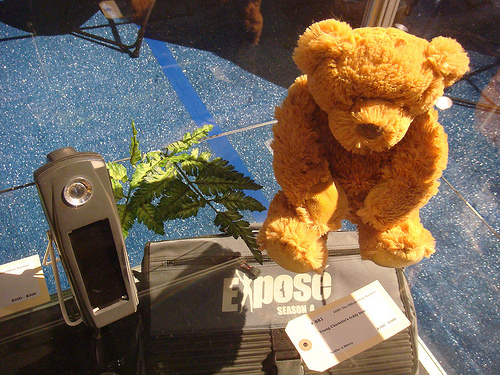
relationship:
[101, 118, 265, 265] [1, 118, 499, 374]
leaves on table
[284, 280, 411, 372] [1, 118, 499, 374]
tag on table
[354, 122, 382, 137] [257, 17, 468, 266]
nose on teddy bear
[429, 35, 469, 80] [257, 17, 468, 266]
ear on teddy bear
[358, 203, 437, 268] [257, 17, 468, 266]
leg on teddy bear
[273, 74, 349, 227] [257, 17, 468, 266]
arm on teddy bear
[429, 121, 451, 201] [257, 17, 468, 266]
light on teddy bear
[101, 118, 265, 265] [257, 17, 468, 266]
leaves beside teddy bear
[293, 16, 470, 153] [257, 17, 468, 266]
face on teddy bear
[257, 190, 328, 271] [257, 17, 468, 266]
leg on teddy bear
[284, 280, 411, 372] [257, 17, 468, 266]
tag by teddy bear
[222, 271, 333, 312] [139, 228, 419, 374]
word on brief case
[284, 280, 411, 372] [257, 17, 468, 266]
tag in front of teddy bear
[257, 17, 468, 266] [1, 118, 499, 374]
teddy bear on table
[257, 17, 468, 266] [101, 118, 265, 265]
teddy bear beside leaves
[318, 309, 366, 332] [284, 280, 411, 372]
words on tag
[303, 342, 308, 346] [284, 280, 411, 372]
hole on tag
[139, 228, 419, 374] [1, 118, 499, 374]
brief case under table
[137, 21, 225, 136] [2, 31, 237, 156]
blue tape on floor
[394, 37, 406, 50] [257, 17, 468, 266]
heart button on teddy bear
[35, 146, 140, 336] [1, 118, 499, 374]
electronic item on table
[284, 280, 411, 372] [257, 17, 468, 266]
tag for teddy bear